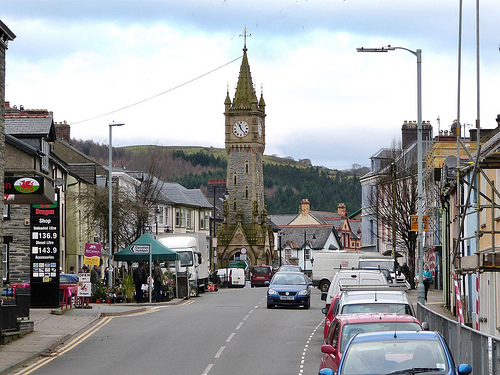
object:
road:
[0, 283, 329, 373]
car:
[320, 312, 434, 375]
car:
[264, 271, 314, 310]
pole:
[416, 47, 421, 294]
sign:
[407, 214, 429, 232]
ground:
[166, 336, 316, 375]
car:
[317, 329, 472, 375]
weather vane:
[237, 24, 253, 54]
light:
[352, 42, 424, 309]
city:
[0, 23, 496, 373]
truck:
[147, 236, 204, 296]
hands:
[237, 122, 245, 135]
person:
[132, 262, 148, 304]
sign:
[130, 245, 149, 253]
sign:
[82, 242, 99, 266]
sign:
[76, 282, 89, 295]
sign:
[3, 177, 44, 195]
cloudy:
[88, 19, 239, 128]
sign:
[28, 187, 60, 309]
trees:
[260, 161, 373, 224]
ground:
[32, 320, 173, 374]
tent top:
[113, 232, 180, 262]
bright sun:
[231, 119, 250, 138]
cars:
[322, 262, 470, 375]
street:
[16, 276, 331, 373]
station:
[0, 110, 66, 326]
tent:
[124, 226, 198, 296]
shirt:
[417, 270, 432, 279]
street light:
[102, 116, 125, 305]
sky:
[22, 11, 220, 103]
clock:
[231, 117, 249, 136]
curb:
[122, 295, 184, 306]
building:
[214, 29, 274, 283]